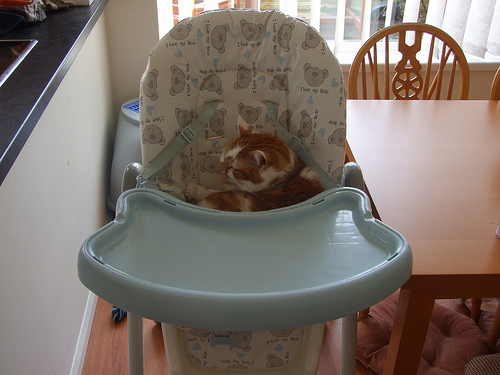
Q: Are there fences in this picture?
A: No, there are no fences.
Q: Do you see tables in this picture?
A: Yes, there is a table.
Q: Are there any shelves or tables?
A: Yes, there is a table.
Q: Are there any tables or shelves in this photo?
A: Yes, there is a table.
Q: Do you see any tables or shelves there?
A: Yes, there is a table.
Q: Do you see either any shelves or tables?
A: Yes, there is a table.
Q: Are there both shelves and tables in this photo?
A: No, there is a table but no shelves.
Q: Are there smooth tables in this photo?
A: Yes, there is a smooth table.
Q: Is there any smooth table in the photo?
A: Yes, there is a smooth table.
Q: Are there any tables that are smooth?
A: Yes, there is a table that is smooth.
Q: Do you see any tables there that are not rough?
A: Yes, there is a smooth table.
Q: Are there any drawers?
A: No, there are no drawers.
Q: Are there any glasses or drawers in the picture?
A: No, there are no drawers or glasses.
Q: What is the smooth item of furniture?
A: The piece of furniture is a table.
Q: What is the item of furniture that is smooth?
A: The piece of furniture is a table.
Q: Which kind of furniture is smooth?
A: The furniture is a table.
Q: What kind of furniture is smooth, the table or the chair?
A: The table is smooth.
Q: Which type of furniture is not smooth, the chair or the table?
A: The chair is not smooth.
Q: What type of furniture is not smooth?
A: The furniture is a chair.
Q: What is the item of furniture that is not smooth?
A: The piece of furniture is a chair.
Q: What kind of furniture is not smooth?
A: The furniture is a chair.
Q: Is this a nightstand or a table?
A: This is a table.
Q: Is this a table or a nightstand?
A: This is a table.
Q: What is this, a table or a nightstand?
A: This is a table.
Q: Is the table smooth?
A: Yes, the table is smooth.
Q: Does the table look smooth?
A: Yes, the table is smooth.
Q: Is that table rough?
A: No, the table is smooth.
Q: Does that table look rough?
A: No, the table is smooth.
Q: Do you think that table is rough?
A: No, the table is smooth.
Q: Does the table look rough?
A: No, the table is smooth.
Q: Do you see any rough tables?
A: No, there is a table but it is smooth.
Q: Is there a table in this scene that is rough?
A: No, there is a table but it is smooth.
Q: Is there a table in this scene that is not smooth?
A: No, there is a table but it is smooth.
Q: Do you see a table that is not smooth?
A: No, there is a table but it is smooth.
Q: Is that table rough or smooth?
A: The table is smooth.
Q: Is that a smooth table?
A: Yes, that is a smooth table.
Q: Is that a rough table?
A: No, that is a smooth table.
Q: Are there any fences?
A: No, there are no fences.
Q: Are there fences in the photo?
A: No, there are no fences.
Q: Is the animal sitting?
A: Yes, the animal is sitting.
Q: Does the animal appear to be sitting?
A: Yes, the animal is sitting.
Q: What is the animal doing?
A: The animal is sitting.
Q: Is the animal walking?
A: No, the animal is sitting.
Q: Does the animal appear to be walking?
A: No, the animal is sitting.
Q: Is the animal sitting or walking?
A: The animal is sitting.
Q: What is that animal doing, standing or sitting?
A: The animal is sitting.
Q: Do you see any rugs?
A: No, there are no rugs.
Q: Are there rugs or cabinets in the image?
A: No, there are no rugs or cabinets.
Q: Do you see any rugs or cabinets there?
A: No, there are no rugs or cabinets.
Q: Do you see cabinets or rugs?
A: No, there are no rugs or cabinets.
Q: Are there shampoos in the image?
A: No, there are no shampoos.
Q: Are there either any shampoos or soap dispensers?
A: No, there are no shampoos or soap dispensers.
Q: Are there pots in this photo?
A: No, there are no pots.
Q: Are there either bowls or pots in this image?
A: No, there are no pots or bowls.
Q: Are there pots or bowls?
A: No, there are no pots or bowls.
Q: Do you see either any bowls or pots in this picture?
A: No, there are no pots or bowls.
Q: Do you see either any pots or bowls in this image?
A: No, there are no pots or bowls.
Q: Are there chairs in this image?
A: Yes, there is a chair.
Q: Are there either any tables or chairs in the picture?
A: Yes, there is a chair.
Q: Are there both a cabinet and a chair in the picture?
A: No, there is a chair but no cabinets.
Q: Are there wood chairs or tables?
A: Yes, there is a wood chair.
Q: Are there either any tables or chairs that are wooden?
A: Yes, the chair is wooden.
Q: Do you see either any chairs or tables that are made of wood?
A: Yes, the chair is made of wood.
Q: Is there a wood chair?
A: Yes, there is a chair that is made of wood.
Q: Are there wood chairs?
A: Yes, there is a chair that is made of wood.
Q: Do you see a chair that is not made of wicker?
A: Yes, there is a chair that is made of wood.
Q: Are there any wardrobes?
A: No, there are no wardrobes.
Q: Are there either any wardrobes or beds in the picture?
A: No, there are no wardrobes or beds.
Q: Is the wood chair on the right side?
A: Yes, the chair is on the right of the image.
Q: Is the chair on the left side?
A: No, the chair is on the right of the image.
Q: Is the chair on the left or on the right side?
A: The chair is on the right of the image.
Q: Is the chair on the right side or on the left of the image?
A: The chair is on the right of the image.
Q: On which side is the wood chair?
A: The chair is on the right of the image.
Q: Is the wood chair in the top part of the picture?
A: Yes, the chair is in the top of the image.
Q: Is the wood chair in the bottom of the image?
A: No, the chair is in the top of the image.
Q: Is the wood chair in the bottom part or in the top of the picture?
A: The chair is in the top of the image.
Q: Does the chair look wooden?
A: Yes, the chair is wooden.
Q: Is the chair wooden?
A: Yes, the chair is wooden.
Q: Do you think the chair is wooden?
A: Yes, the chair is wooden.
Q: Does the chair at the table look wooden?
A: Yes, the chair is wooden.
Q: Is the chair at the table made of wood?
A: Yes, the chair is made of wood.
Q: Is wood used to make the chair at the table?
A: Yes, the chair is made of wood.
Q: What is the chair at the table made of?
A: The chair is made of wood.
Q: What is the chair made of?
A: The chair is made of wood.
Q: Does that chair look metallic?
A: No, the chair is wooden.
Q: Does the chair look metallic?
A: No, the chair is wooden.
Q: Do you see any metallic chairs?
A: No, there is a chair but it is wooden.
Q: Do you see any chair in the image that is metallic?
A: No, there is a chair but it is wooden.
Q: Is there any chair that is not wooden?
A: No, there is a chair but it is wooden.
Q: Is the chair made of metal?
A: No, the chair is made of wood.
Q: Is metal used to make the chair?
A: No, the chair is made of wood.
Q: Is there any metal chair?
A: No, there is a chair but it is made of wood.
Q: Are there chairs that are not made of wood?
A: No, there is a chair but it is made of wood.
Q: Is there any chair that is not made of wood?
A: No, there is a chair but it is made of wood.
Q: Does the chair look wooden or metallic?
A: The chair is wooden.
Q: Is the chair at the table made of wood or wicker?
A: The chair is made of wood.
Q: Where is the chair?
A: The chair is at the table.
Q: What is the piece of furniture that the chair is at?
A: The piece of furniture is a table.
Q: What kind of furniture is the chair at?
A: The chair is at the table.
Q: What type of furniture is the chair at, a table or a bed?
A: The chair is at a table.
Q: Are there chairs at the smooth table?
A: Yes, there is a chair at the table.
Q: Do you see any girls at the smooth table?
A: No, there is a chair at the table.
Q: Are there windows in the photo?
A: Yes, there are windows.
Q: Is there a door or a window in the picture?
A: Yes, there are windows.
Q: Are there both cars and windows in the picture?
A: No, there are windows but no cars.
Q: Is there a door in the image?
A: No, there are no doors.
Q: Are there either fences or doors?
A: No, there are no doors or fences.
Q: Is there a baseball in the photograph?
A: No, there are no baseballs.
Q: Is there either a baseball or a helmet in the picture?
A: No, there are no baseballs or helmets.